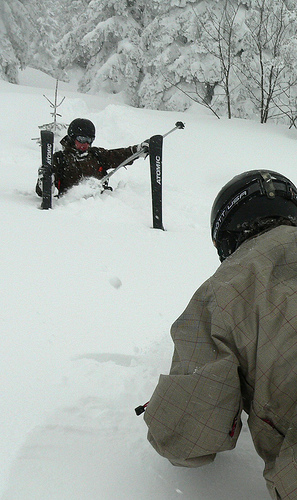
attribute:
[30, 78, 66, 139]
pinetree — small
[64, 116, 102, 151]
helmet — black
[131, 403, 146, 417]
tag — black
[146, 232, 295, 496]
coat — tan plaid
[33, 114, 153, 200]
person — fallen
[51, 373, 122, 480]
snow — fresh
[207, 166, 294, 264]
helmet — black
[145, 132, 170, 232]
ski — sticking, black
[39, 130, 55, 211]
ski — black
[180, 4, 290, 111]
trees — leafless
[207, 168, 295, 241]
helmet — black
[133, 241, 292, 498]
jacket — brown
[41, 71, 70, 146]
tree — small 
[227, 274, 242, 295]
line — red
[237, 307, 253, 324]
line — red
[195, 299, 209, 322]
line — red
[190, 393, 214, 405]
line — red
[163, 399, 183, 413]
line — red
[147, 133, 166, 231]
ski — black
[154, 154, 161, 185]
writing — white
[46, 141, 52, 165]
writing — white